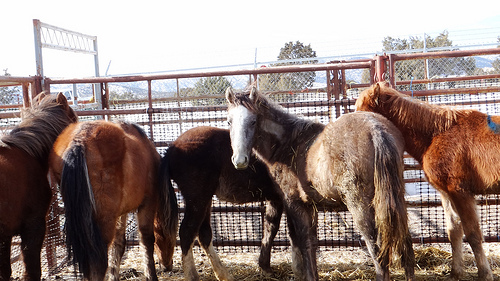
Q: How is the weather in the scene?
A: It is clear.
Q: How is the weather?
A: It is clear.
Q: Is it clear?
A: Yes, it is clear.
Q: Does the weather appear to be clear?
A: Yes, it is clear.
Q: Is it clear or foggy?
A: It is clear.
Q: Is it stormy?
A: No, it is clear.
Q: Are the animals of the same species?
A: Yes, all the animals are horses.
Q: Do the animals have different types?
A: No, all the animals are horses.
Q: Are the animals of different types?
A: No, all the animals are horses.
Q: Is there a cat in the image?
A: No, there are no cats.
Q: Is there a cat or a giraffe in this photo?
A: No, there are no cats or giraffes.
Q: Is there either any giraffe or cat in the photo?
A: No, there are no cats or giraffes.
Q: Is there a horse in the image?
A: Yes, there is a horse.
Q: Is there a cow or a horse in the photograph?
A: Yes, there is a horse.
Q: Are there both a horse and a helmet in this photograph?
A: No, there is a horse but no helmets.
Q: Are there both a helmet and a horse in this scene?
A: No, there is a horse but no helmets.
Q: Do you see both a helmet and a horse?
A: No, there is a horse but no helmets.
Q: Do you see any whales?
A: No, there are no whales.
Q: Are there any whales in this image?
A: No, there are no whales.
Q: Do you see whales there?
A: No, there are no whales.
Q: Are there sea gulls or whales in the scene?
A: No, there are no whales or sea gulls.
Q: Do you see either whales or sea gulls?
A: No, there are no whales or sea gulls.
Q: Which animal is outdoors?
A: The animal is a horse.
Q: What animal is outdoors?
A: The animal is a horse.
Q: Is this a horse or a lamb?
A: This is a horse.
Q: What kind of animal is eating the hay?
A: The animal is a horse.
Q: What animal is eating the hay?
A: The horse is eating the hay.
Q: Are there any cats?
A: No, there are no cats.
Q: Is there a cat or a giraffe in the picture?
A: No, there are no cats or giraffes.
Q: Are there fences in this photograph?
A: Yes, there is a fence.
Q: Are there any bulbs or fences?
A: Yes, there is a fence.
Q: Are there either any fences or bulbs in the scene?
A: Yes, there is a fence.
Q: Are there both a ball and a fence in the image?
A: No, there is a fence but no balls.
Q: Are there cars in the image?
A: No, there are no cars.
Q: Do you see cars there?
A: No, there are no cars.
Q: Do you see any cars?
A: No, there are no cars.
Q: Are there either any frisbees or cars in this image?
A: No, there are no cars or frisbees.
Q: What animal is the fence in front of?
A: The fence is in front of the horses.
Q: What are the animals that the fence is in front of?
A: The animals are horses.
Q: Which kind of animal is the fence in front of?
A: The fence is in front of the horses.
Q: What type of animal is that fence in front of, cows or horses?
A: The fence is in front of horses.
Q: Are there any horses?
A: Yes, there is a horse.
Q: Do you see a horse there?
A: Yes, there is a horse.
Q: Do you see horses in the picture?
A: Yes, there is a horse.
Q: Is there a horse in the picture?
A: Yes, there is a horse.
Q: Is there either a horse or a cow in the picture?
A: Yes, there is a horse.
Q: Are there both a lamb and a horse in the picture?
A: No, there is a horse but no lambs.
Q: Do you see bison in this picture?
A: No, there are no bison.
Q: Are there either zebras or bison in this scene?
A: No, there are no bison or zebras.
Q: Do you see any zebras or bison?
A: No, there are no bison or zebras.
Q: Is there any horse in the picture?
A: Yes, there is a horse.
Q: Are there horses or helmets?
A: Yes, there is a horse.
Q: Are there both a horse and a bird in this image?
A: No, there is a horse but no birds.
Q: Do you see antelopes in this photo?
A: No, there are no antelopes.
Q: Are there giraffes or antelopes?
A: No, there are no antelopes or giraffes.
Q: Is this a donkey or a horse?
A: This is a horse.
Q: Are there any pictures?
A: No, there are no pictures.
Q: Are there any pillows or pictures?
A: No, there are no pictures or pillows.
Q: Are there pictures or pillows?
A: No, there are no pictures or pillows.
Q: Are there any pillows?
A: No, there are no pillows.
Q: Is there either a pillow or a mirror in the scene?
A: No, there are no pillows or mirrors.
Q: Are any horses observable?
A: Yes, there is a horse.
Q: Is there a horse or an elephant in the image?
A: Yes, there is a horse.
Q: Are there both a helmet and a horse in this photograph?
A: No, there is a horse but no helmets.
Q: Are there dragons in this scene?
A: No, there are no dragons.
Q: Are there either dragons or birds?
A: No, there are no dragons or birds.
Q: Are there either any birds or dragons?
A: No, there are no dragons or birds.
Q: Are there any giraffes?
A: No, there are no giraffes.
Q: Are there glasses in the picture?
A: No, there are no glasses.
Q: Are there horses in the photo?
A: Yes, there are horses.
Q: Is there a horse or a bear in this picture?
A: Yes, there are horses.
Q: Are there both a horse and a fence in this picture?
A: Yes, there are both a horse and a fence.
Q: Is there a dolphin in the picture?
A: No, there are no dolphins.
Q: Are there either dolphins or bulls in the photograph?
A: No, there are no dolphins or bulls.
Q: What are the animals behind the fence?
A: The animals are horses.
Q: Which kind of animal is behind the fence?
A: The animals are horses.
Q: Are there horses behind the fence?
A: Yes, there are horses behind the fence.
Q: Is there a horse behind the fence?
A: Yes, there are horses behind the fence.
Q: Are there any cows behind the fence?
A: No, there are horses behind the fence.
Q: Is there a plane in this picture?
A: No, there are no airplanes.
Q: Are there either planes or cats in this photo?
A: No, there are no planes or cats.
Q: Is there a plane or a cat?
A: No, there are no airplanes or cats.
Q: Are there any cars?
A: No, there are no cars.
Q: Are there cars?
A: No, there are no cars.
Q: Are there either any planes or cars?
A: No, there are no cars or planes.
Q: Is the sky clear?
A: Yes, the sky is clear.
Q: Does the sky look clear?
A: Yes, the sky is clear.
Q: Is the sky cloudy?
A: No, the sky is clear.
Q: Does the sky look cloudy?
A: No, the sky is clear.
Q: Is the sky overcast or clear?
A: The sky is clear.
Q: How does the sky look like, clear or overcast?
A: The sky is clear.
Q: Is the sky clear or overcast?
A: The sky is clear.